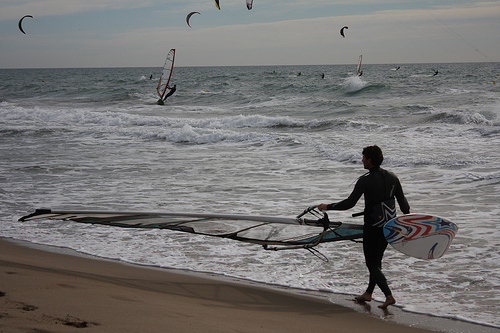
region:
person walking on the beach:
[305, 130, 405, 324]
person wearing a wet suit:
[308, 134, 398, 316]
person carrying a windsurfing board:
[13, 139, 463, 314]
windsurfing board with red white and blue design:
[16, 185, 461, 275]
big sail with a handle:
[17, 193, 363, 270]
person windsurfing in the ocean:
[150, 39, 183, 114]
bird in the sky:
[337, 22, 354, 44]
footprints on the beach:
[8, 278, 105, 331]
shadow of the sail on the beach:
[5, 258, 357, 321]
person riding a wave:
[341, 43, 372, 100]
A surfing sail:
[168, 58, 171, 72]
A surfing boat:
[160, 98, 163, 103]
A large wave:
[350, 78, 362, 88]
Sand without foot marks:
[178, 298, 242, 328]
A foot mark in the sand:
[64, 318, 86, 328]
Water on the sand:
[403, 317, 438, 323]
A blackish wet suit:
[370, 185, 380, 198]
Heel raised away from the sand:
[390, 297, 395, 302]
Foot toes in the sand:
[377, 302, 382, 307]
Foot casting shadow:
[385, 310, 391, 315]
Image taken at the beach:
[14, 18, 494, 305]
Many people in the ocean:
[18, 22, 493, 157]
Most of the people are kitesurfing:
[15, 26, 482, 164]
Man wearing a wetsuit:
[338, 146, 425, 301]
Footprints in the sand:
[10, 276, 106, 331]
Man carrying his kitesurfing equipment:
[13, 139, 484, 282]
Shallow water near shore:
[36, 147, 325, 255]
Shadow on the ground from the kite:
[88, 253, 339, 332]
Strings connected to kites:
[188, 13, 340, 58]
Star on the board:
[425, 211, 468, 238]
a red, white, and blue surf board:
[381, 213, 460, 260]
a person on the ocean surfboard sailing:
[155, 47, 180, 104]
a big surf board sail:
[17, 202, 356, 252]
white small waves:
[3, 100, 313, 148]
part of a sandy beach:
[1, 232, 346, 332]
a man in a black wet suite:
[317, 143, 407, 308]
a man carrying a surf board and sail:
[15, 145, 455, 313]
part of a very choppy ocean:
[8, 64, 498, 194]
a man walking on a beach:
[319, 145, 410, 313]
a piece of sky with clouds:
[4, 1, 496, 63]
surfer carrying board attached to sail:
[16, 140, 462, 311]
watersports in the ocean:
[15, 1, 450, 111]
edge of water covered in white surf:
[5, 85, 495, 325]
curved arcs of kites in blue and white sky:
[12, 0, 349, 40]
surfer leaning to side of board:
[152, 40, 177, 107]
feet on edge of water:
[345, 255, 396, 315]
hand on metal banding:
[291, 197, 331, 222]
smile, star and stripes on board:
[380, 210, 455, 261]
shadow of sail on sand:
[2, 250, 348, 325]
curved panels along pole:
[18, 200, 361, 251]